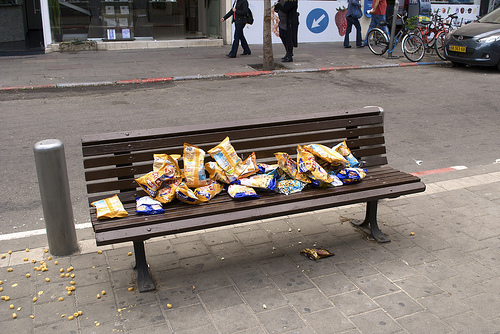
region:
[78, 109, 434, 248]
several bags of snacks on a bench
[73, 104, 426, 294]
wooden and metal bench with bags on top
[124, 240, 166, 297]
bottom metal leg of outdoor bench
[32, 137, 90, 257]
one short wide metal pole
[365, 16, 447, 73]
several bicycles parked on sidewalk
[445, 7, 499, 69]
front of dark sedan parked at curb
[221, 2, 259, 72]
pedestrian walking down sidewalk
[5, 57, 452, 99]
section of curb painted red and white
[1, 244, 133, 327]
bits of snack food scattered on pavement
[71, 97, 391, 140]
top edge of bench with street in background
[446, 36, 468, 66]
a tag on a car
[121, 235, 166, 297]
legs on a bench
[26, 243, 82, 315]
food on the ground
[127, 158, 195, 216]
chips on a bench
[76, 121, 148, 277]
a bench beside the street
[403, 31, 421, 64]
a tire on a bike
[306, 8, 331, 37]
an arrow on a wall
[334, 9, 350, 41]
a strawberry on a wall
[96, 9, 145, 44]
papers on a stand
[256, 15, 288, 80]
a tree beside the street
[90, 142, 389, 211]
yellow bags of chips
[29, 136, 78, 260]
a gray concrete post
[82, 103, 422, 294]
a brown and black bench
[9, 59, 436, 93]
a red and gray curb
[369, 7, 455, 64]
bike cycles on a side walk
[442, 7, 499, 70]
a car parked on the street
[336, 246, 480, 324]
a blocked concrete side walk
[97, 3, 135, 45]
white labels in a window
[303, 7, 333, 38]
a white arrow on the wall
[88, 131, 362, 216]
bags of chips on bench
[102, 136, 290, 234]
unopened bags of chips on walkway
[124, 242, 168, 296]
black metal bottom of bench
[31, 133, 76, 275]
small silver pole on sidewalk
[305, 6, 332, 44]
blue sign on the wall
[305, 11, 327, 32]
white arrow on the sign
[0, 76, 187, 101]
red and white curb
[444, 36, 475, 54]
yellow licence plate of car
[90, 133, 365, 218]
Several plastic packets of chips or cheese balls left on a bench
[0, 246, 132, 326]
Some cheese pops fallen on ground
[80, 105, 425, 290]
Brown bench on a sidewalk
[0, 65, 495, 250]
Small road of a town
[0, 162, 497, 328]
Tiled sidewalk of the road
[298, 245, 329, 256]
One snack packet fallen on the ground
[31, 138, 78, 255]
One short pole by the roadside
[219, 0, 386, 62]
A few people on the sidewalk of the far side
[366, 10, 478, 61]
Some bicycles parked on the sidewalk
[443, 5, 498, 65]
A blue parked car on the far side of the road